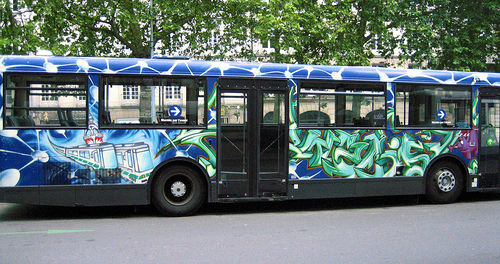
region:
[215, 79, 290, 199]
the doors of a bus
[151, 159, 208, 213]
a black bus tire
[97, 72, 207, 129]
the window of a bus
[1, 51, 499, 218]
a long blue bus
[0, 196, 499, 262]
a gray road under the bus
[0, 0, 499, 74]
green trees behind the bus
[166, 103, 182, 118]
a blue and white arrow sign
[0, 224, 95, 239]
a green arrow on the ground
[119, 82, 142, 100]
the window of a building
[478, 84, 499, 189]
a door on the bus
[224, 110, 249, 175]
part of the rare door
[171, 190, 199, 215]
part of a rare wheel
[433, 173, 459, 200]
part of a front wheel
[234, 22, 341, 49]
part of some green leaves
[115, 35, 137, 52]
part of a tree branch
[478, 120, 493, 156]
part of a front door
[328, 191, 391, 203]
edge of a bus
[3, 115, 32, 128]
part of some back seats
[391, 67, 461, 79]
top edge of a bus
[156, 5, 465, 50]
these are leaves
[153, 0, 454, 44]
the leaves are green in color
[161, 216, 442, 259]
this is a road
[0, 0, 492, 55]
these are trees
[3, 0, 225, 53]
the trees have branches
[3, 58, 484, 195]
this is a bus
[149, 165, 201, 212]
this is a Tyre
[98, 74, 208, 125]
this is the window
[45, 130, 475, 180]
the bus is painted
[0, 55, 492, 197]
the big is big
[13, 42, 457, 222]
the bus is parked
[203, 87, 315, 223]
the door is black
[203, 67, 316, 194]
the door is open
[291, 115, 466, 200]
the graffiti art is green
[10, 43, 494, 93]
the roof is blue and white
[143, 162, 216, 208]
the tire is black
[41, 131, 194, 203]
two train drawings on the exterior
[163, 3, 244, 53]
the trees are green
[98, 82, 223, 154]
the window is transparent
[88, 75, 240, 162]
the window is made of glass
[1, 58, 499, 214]
A large bus painted mostly blue and white in the street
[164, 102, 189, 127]
An arrow painted white with a blue background on the bus window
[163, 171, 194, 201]
The small white circular hubcap of the bus wheel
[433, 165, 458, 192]
The larger hubcap of the bus wheel with dark dots around it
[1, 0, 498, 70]
Trees with green leaves over the bus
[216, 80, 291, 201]
The black backdoor of the bus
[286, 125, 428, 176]
A light green chain-like image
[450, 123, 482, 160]
A purple image with spots of white near the front door of the bus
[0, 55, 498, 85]
The top of the bus in blue and white designs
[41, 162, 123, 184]
Black lines painted like small gates near the back of the bus